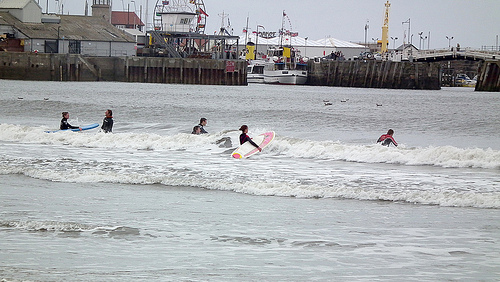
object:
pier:
[1, 1, 499, 61]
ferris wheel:
[151, 3, 208, 33]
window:
[408, 138, 481, 205]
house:
[0, 13, 137, 43]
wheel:
[230, 131, 275, 159]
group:
[58, 108, 402, 154]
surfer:
[377, 129, 398, 147]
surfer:
[238, 125, 263, 153]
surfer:
[191, 126, 201, 134]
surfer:
[198, 118, 209, 134]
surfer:
[60, 111, 82, 131]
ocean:
[1, 77, 498, 279]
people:
[101, 109, 114, 134]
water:
[2, 89, 498, 278]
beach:
[10, 37, 497, 104]